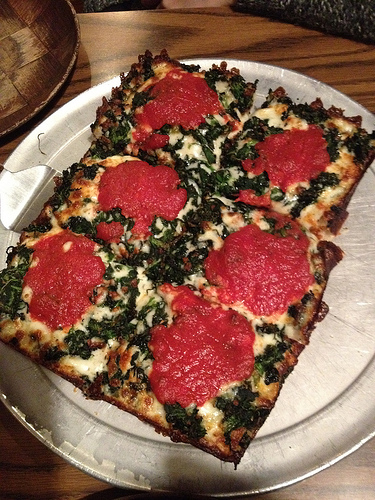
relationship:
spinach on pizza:
[3, 52, 374, 425] [3, 44, 371, 497]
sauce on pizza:
[241, 121, 337, 192] [3, 44, 371, 497]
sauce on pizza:
[92, 147, 194, 238] [3, 44, 371, 497]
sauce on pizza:
[131, 60, 223, 150] [3, 44, 371, 497]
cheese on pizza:
[79, 350, 120, 380] [37, 132, 278, 374]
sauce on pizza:
[131, 68, 225, 151] [106, 41, 233, 169]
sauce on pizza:
[231, 123, 333, 208] [3, 44, 371, 497]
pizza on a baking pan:
[3, 44, 371, 497] [292, 375, 362, 490]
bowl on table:
[0, 4, 78, 129] [90, 13, 145, 46]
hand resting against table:
[161, 3, 232, 14] [4, 8, 372, 489]